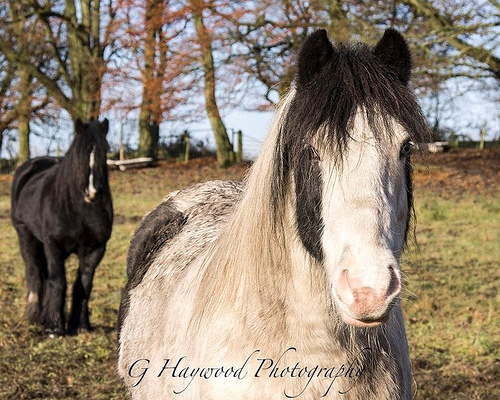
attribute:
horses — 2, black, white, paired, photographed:
[3, 66, 443, 317]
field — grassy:
[416, 180, 492, 331]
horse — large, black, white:
[4, 130, 125, 341]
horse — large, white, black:
[272, 60, 424, 298]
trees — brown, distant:
[39, 17, 288, 108]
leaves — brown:
[158, 10, 197, 20]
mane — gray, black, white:
[321, 62, 403, 88]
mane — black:
[80, 124, 113, 143]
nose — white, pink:
[341, 278, 392, 321]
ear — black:
[297, 32, 339, 84]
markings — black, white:
[141, 202, 188, 245]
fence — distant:
[150, 130, 222, 150]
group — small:
[16, 8, 219, 143]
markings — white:
[91, 141, 103, 198]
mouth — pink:
[328, 310, 424, 325]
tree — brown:
[193, 10, 241, 155]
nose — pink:
[343, 263, 399, 311]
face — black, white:
[73, 130, 111, 198]